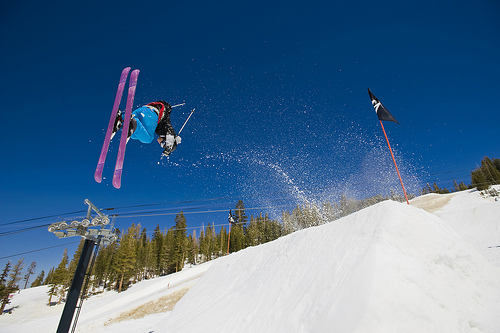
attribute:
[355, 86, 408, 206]
flag pole — pink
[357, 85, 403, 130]
flag — black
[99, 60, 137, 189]
skis — pink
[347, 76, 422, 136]
flag — black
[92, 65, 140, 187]
skis — pink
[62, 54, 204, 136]
person — air born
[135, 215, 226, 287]
tree — evergreen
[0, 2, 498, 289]
sky — clear, blue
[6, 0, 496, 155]
sky — blue, dark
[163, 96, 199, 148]
ski poles — silver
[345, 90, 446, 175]
flag — black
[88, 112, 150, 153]
pants — blue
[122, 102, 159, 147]
pants — blue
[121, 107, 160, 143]
pants — blue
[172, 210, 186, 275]
tree — yellow, green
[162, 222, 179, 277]
tree — yellow, green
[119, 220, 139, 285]
tree — yellow, green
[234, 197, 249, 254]
tree — yellow, green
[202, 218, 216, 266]
tree — yellow, green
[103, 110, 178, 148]
pants — blue